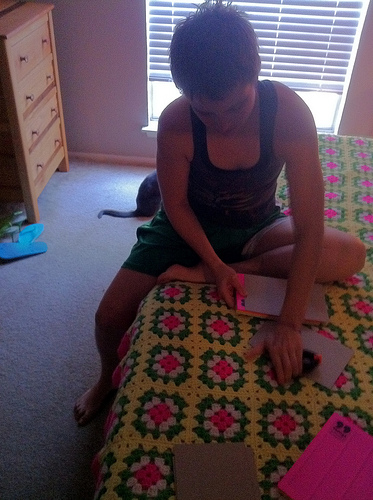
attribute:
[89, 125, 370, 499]
blanket — crocheted, yellow, pink, green, pretty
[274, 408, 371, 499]
paper — pink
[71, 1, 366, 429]
boy — barefoot, sitting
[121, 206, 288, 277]
shorts — green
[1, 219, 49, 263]
flip flops — blue, green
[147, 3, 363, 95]
blind — open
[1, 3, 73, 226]
dresser — wood, wooden, brown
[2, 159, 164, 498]
floor — carpeted, gray, white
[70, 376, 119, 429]
right foot — white